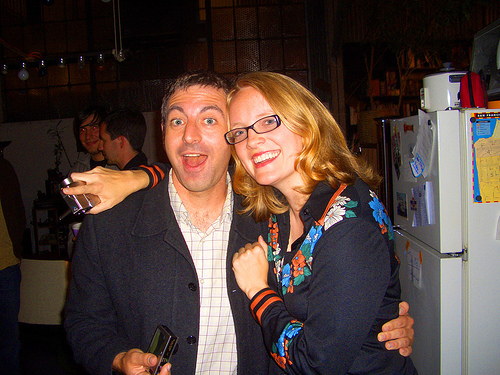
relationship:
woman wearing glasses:
[226, 79, 411, 370] [222, 115, 284, 147]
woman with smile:
[226, 79, 411, 370] [246, 148, 284, 169]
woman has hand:
[226, 79, 411, 370] [241, 230, 379, 372]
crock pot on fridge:
[419, 60, 472, 111] [381, 105, 499, 374]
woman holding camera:
[226, 79, 411, 370] [56, 168, 105, 215]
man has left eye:
[68, 74, 281, 375] [198, 109, 222, 133]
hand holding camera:
[60, 159, 172, 216] [56, 168, 105, 215]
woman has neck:
[226, 79, 411, 370] [267, 167, 329, 232]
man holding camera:
[68, 74, 281, 375] [145, 326, 178, 370]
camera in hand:
[145, 326, 178, 370] [108, 340, 177, 374]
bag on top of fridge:
[455, 70, 483, 107] [381, 105, 499, 374]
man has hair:
[68, 74, 281, 375] [157, 66, 236, 110]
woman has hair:
[226, 79, 411, 370] [225, 67, 371, 194]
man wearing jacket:
[68, 74, 281, 375] [65, 187, 286, 375]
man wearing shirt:
[68, 74, 281, 375] [171, 181, 252, 374]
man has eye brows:
[68, 74, 281, 375] [161, 117, 192, 128]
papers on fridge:
[388, 112, 496, 238] [381, 105, 499, 374]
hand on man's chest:
[241, 230, 379, 372] [217, 197, 279, 330]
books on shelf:
[399, 44, 467, 72] [338, 30, 478, 165]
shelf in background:
[338, 30, 478, 165] [10, 16, 495, 358]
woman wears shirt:
[226, 79, 411, 370] [246, 188, 397, 369]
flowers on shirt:
[258, 209, 393, 296] [246, 188, 397, 369]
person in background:
[70, 110, 111, 201] [10, 16, 495, 358]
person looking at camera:
[70, 110, 111, 201] [26, 31, 409, 225]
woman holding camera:
[226, 79, 411, 370] [60, 168, 105, 215]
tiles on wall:
[3, 2, 312, 101] [1, 6, 325, 234]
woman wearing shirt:
[226, 79, 411, 370] [246, 188, 397, 369]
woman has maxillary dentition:
[226, 79, 411, 370] [246, 148, 284, 169]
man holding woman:
[68, 74, 281, 375] [226, 79, 411, 370]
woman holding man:
[226, 79, 411, 370] [68, 74, 281, 375]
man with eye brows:
[68, 74, 281, 375] [161, 117, 192, 128]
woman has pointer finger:
[226, 79, 411, 370] [60, 181, 107, 199]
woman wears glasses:
[226, 79, 411, 370] [222, 115, 284, 147]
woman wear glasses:
[226, 79, 411, 370] [222, 115, 284, 147]